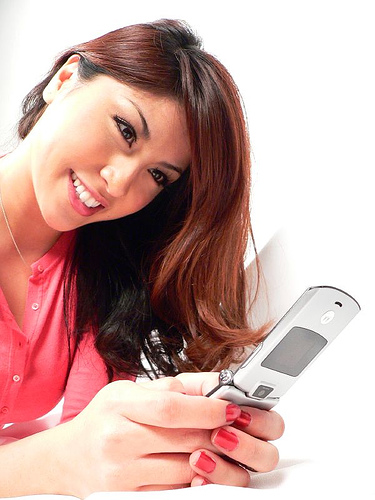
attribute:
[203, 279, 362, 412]
phone — held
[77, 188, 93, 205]
tooth — white, human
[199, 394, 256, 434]
fingernail — red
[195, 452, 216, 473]
polish — red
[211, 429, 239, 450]
polish — red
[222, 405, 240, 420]
polish — red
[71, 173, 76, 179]
human tooth — white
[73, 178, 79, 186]
human tooth — white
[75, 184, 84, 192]
human tooth — white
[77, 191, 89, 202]
human tooth — white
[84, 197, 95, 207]
human tooth — white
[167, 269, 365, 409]
phone — flip top, razr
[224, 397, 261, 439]
fingernail — red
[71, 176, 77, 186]
tooth — white, human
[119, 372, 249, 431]
finger — human, white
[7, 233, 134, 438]
shirt — pink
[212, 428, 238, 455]
fingernail — red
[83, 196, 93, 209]
tooth — white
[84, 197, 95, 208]
teeth — white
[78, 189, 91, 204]
teeth — white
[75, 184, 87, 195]
teeth — white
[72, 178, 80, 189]
teeth — white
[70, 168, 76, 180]
teeth — white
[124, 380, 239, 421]
human finger — white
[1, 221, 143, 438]
blouse — tiny, pink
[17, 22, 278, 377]
hair — long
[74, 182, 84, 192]
tooth — human, white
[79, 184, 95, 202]
human tooth — white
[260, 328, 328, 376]
window — grey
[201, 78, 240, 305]
highlights — light, brown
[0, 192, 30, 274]
necklace — thin, silver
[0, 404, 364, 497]
blanket — white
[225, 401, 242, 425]
fingernail — red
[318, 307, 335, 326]
logo — circle